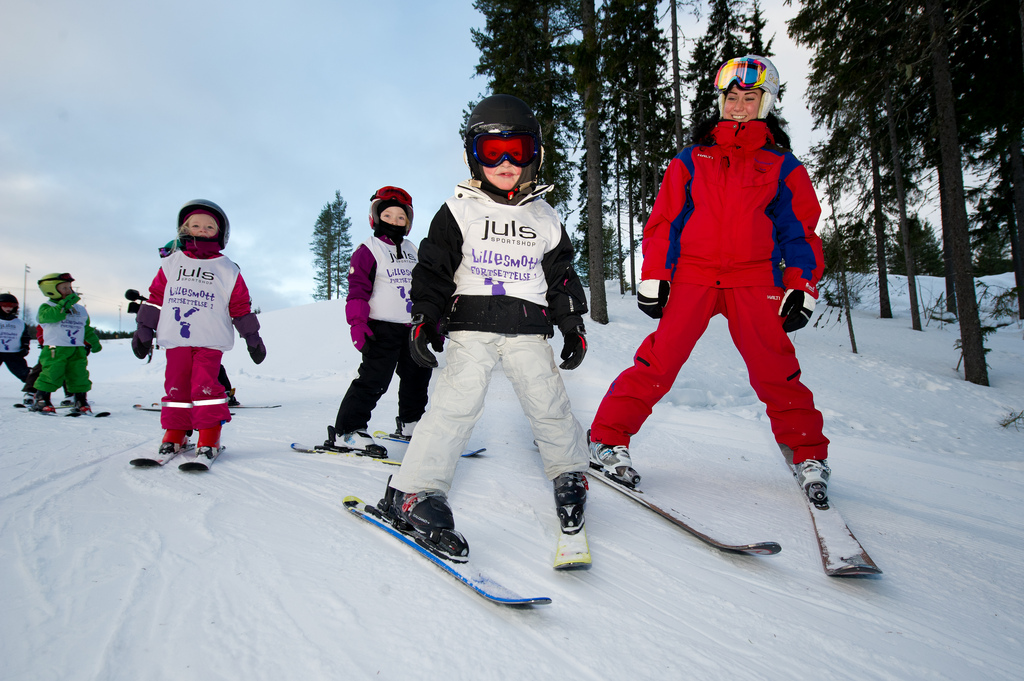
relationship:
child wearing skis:
[130, 195, 268, 456] [132, 444, 225, 476]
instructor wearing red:
[588, 53, 843, 507] [588, 120, 831, 460]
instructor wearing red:
[588, 53, 843, 507] [591, 120, 830, 464]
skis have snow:
[585, 465, 887, 582] [604, 470, 868, 566]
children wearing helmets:
[0, 90, 600, 560] [0, 49, 781, 314]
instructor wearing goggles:
[588, 53, 843, 507] [713, 56, 767, 94]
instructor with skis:
[588, 53, 843, 507] [585, 465, 887, 582]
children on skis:
[0, 90, 600, 560] [0, 385, 881, 607]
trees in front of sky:
[310, 0, 1023, 387] [2, 2, 496, 338]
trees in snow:
[310, 0, 1023, 387] [264, 12, 1016, 678]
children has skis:
[339, 96, 589, 605] [132, 444, 225, 476]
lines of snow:
[586, 584, 740, 669] [0, 263, 1021, 679]